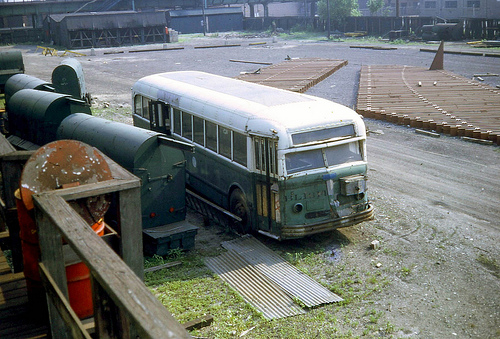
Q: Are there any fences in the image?
A: Yes, there is a fence.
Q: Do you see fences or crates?
A: Yes, there is a fence.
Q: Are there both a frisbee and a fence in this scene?
A: No, there is a fence but no frisbees.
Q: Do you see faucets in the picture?
A: No, there are no faucets.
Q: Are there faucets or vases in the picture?
A: No, there are no faucets or vases.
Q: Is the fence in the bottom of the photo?
A: Yes, the fence is in the bottom of the image.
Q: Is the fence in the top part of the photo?
A: No, the fence is in the bottom of the image.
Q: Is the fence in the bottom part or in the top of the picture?
A: The fence is in the bottom of the image.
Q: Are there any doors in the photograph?
A: Yes, there is a door.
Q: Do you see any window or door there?
A: Yes, there is a door.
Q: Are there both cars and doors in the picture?
A: No, there is a door but no cars.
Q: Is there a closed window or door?
A: Yes, there is a closed door.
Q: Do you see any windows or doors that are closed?
A: Yes, the door is closed.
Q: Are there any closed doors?
A: Yes, there is a closed door.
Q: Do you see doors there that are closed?
A: Yes, there is a door that is closed.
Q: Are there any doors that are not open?
A: Yes, there is an closed door.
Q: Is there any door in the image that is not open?
A: Yes, there is an closed door.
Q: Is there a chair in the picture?
A: No, there are no chairs.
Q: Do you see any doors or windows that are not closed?
A: No, there is a door but it is closed.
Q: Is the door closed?
A: Yes, the door is closed.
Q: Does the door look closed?
A: Yes, the door is closed.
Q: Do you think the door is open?
A: No, the door is closed.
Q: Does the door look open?
A: No, the door is closed.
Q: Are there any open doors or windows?
A: No, there is a door but it is closed.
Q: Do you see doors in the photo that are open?
A: No, there is a door but it is closed.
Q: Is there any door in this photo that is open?
A: No, there is a door but it is closed.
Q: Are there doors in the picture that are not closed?
A: No, there is a door but it is closed.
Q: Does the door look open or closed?
A: The door is closed.